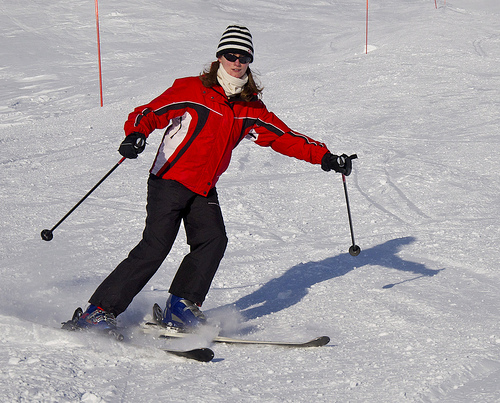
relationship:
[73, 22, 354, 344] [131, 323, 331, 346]
woman wearing skiis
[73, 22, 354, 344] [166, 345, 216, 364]
woman wearing skiis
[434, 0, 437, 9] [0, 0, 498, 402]
marker on trail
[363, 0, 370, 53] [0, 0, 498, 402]
marker on trail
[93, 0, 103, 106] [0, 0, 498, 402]
marker on trail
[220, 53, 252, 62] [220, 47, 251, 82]
sunglasses on face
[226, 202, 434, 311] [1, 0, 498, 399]
shadow on ground